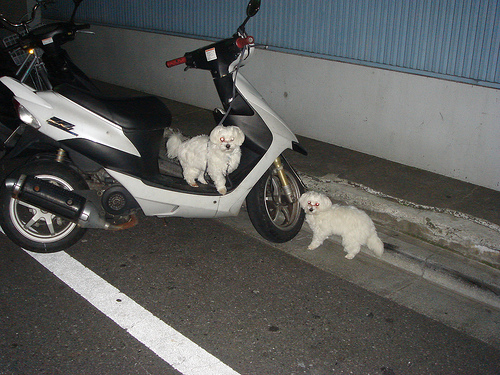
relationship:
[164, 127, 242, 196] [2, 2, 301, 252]
dog on bike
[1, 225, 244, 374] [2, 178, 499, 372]
line on ground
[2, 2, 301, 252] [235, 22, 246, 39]
bike has mirror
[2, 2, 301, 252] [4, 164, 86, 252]
bike has a tire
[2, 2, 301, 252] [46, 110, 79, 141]
bike has label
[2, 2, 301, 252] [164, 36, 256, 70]
bike has a handles